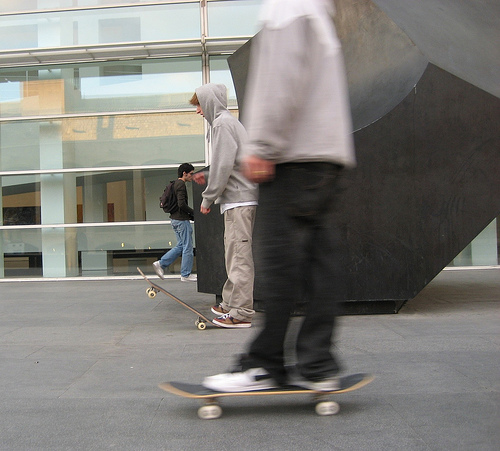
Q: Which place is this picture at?
A: It is at the sidewalk.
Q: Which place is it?
A: It is a sidewalk.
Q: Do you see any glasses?
A: No, there are no glasses.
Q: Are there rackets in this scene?
A: No, there are no rackets.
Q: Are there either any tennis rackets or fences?
A: No, there are no tennis rackets or fences.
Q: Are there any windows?
A: Yes, there is a window.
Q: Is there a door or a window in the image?
A: Yes, there is a window.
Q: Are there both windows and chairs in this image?
A: No, there is a window but no chairs.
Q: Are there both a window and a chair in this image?
A: No, there is a window but no chairs.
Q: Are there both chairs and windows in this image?
A: No, there is a window but no chairs.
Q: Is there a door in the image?
A: No, there are no doors.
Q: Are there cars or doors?
A: No, there are no doors or cars.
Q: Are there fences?
A: No, there are no fences.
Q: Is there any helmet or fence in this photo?
A: No, there are no fences or helmets.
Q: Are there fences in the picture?
A: No, there are no fences.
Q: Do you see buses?
A: No, there are no buses.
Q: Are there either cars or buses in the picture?
A: No, there are no buses or cars.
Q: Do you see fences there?
A: No, there are no fences.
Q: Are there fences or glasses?
A: No, there are no fences or glasses.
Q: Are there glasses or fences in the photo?
A: No, there are no fences or glasses.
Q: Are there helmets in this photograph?
A: No, there are no helmets.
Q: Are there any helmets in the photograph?
A: No, there are no helmets.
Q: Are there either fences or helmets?
A: No, there are no helmets or fences.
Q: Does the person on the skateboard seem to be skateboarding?
A: Yes, the person is skateboarding.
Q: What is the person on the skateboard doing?
A: The person is skateboarding.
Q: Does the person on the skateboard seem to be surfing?
A: No, the person is skateboarding.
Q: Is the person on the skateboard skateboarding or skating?
A: The person is skateboarding.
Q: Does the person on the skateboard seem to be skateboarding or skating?
A: The person is skateboarding.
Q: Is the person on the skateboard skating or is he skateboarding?
A: The person is skateboarding.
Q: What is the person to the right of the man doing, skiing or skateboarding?
A: The person is skateboarding.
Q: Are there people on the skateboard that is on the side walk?
A: Yes, there is a person on the skateboard.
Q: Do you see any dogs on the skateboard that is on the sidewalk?
A: No, there is a person on the skateboard.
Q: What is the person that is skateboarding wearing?
A: The person is wearing trousers.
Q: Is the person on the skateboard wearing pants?
A: Yes, the person is wearing pants.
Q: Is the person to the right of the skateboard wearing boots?
A: No, the person is wearing pants.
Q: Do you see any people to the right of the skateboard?
A: Yes, there is a person to the right of the skateboard.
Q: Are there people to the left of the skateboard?
A: No, the person is to the right of the skateboard.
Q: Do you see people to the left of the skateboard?
A: No, the person is to the right of the skateboard.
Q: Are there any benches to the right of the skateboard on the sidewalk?
A: No, there is a person to the right of the skateboard.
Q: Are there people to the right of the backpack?
A: Yes, there is a person to the right of the backpack.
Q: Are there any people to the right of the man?
A: Yes, there is a person to the right of the man.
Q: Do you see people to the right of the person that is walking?
A: Yes, there is a person to the right of the man.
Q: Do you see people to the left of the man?
A: No, the person is to the right of the man.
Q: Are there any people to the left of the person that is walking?
A: No, the person is to the right of the man.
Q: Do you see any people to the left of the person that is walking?
A: No, the person is to the right of the man.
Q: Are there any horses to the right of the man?
A: No, there is a person to the right of the man.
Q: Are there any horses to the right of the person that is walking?
A: No, there is a person to the right of the man.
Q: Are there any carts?
A: No, there are no carts.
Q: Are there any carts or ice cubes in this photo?
A: No, there are no carts or ice cubes.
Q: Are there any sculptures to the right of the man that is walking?
A: Yes, there is a sculpture to the right of the man.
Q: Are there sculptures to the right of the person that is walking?
A: Yes, there is a sculpture to the right of the man.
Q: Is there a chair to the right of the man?
A: No, there is a sculpture to the right of the man.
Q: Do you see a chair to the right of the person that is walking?
A: No, there is a sculpture to the right of the man.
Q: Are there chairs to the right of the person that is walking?
A: No, there is a sculpture to the right of the man.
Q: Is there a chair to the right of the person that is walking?
A: No, there is a sculpture to the right of the man.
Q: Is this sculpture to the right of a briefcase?
A: No, the sculpture is to the right of a backpack.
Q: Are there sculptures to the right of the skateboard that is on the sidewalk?
A: Yes, there is a sculpture to the right of the skateboard.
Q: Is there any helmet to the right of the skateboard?
A: No, there is a sculpture to the right of the skateboard.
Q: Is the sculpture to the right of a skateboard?
A: Yes, the sculpture is to the right of a skateboard.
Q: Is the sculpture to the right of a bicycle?
A: No, the sculpture is to the right of a skateboard.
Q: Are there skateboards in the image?
A: Yes, there is a skateboard.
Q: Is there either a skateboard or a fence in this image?
A: Yes, there is a skateboard.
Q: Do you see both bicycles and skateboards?
A: No, there is a skateboard but no bicycles.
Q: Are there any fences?
A: No, there are no fences.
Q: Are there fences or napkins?
A: No, there are no fences or napkins.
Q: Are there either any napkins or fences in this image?
A: No, there are no fences or napkins.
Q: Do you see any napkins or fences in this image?
A: No, there are no fences or napkins.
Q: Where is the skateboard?
A: The skateboard is on the sidewalk.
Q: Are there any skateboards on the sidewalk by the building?
A: Yes, there is a skateboard on the sidewalk.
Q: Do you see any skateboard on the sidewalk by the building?
A: Yes, there is a skateboard on the sidewalk.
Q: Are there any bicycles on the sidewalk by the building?
A: No, there is a skateboard on the sidewalk.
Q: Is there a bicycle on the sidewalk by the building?
A: No, there is a skateboard on the sidewalk.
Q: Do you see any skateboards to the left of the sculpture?
A: Yes, there is a skateboard to the left of the sculpture.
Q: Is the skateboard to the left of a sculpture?
A: Yes, the skateboard is to the left of a sculpture.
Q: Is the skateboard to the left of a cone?
A: No, the skateboard is to the left of a sculpture.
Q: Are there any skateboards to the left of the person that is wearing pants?
A: Yes, there is a skateboard to the left of the person.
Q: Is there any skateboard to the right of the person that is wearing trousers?
A: No, the skateboard is to the left of the person.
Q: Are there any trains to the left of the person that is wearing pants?
A: No, there is a skateboard to the left of the person.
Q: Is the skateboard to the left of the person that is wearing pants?
A: Yes, the skateboard is to the left of the person.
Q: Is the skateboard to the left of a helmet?
A: No, the skateboard is to the left of the person.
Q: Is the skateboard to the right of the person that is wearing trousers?
A: No, the skateboard is to the left of the person.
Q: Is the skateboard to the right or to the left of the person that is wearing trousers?
A: The skateboard is to the left of the person.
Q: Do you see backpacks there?
A: Yes, there is a backpack.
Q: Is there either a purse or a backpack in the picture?
A: Yes, there is a backpack.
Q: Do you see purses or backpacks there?
A: Yes, there is a backpack.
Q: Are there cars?
A: No, there are no cars.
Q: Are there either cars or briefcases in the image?
A: No, there are no cars or briefcases.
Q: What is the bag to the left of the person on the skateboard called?
A: The bag is a backpack.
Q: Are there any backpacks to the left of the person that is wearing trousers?
A: Yes, there is a backpack to the left of the person.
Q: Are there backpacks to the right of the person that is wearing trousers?
A: No, the backpack is to the left of the person.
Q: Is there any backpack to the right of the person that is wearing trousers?
A: No, the backpack is to the left of the person.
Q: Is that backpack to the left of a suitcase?
A: No, the backpack is to the left of the person.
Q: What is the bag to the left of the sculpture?
A: The bag is a backpack.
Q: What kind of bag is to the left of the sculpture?
A: The bag is a backpack.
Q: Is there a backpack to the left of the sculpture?
A: Yes, there is a backpack to the left of the sculpture.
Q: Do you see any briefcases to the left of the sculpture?
A: No, there is a backpack to the left of the sculpture.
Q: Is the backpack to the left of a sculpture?
A: Yes, the backpack is to the left of a sculpture.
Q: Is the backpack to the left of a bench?
A: No, the backpack is to the left of a sculpture.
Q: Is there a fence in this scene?
A: No, there are no fences.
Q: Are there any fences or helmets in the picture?
A: No, there are no fences or helmets.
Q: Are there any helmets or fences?
A: No, there are no fences or helmets.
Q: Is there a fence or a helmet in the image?
A: No, there are no fences or helmets.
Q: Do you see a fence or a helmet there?
A: No, there are no fences or helmets.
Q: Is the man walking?
A: Yes, the man is walking.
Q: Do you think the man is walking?
A: Yes, the man is walking.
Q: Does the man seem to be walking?
A: Yes, the man is walking.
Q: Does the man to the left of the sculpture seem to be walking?
A: Yes, the man is walking.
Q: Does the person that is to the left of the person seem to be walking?
A: Yes, the man is walking.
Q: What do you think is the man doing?
A: The man is walking.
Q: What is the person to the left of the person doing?
A: The man is walking.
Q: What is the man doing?
A: The man is walking.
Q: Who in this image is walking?
A: The man is walking.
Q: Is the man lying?
A: No, the man is walking.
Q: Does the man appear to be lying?
A: No, the man is walking.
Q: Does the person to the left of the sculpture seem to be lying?
A: No, the man is walking.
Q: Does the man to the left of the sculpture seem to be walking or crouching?
A: The man is walking.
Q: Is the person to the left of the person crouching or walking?
A: The man is walking.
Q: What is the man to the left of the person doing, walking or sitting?
A: The man is walking.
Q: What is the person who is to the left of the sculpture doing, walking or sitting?
A: The man is walking.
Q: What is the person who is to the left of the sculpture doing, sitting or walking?
A: The man is walking.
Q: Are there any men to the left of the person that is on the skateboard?
A: Yes, there is a man to the left of the person.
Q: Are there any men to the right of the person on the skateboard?
A: No, the man is to the left of the person.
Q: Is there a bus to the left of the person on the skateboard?
A: No, there is a man to the left of the person.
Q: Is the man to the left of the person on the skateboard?
A: Yes, the man is to the left of the person.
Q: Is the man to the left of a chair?
A: No, the man is to the left of the person.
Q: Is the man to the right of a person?
A: No, the man is to the left of a person.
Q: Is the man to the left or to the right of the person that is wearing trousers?
A: The man is to the left of the person.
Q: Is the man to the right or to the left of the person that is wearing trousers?
A: The man is to the left of the person.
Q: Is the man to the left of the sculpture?
A: Yes, the man is to the left of the sculpture.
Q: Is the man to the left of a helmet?
A: No, the man is to the left of the sculpture.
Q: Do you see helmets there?
A: No, there are no helmets.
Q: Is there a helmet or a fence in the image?
A: No, there are no helmets or fences.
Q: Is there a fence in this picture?
A: No, there are no fences.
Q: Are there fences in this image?
A: No, there are no fences.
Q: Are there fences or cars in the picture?
A: No, there are no fences or cars.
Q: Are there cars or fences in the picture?
A: No, there are no fences or cars.